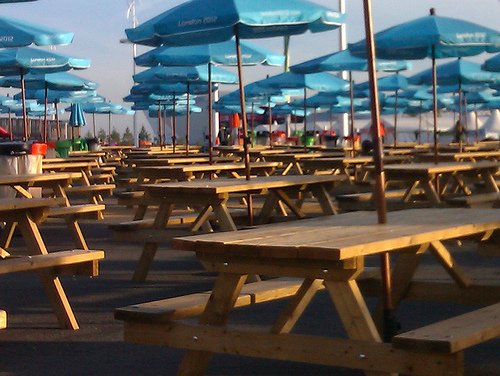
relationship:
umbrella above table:
[125, 1, 347, 37] [108, 144, 350, 279]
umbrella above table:
[0, 17, 70, 51] [4, 170, 105, 259]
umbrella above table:
[348, 6, 498, 58] [338, 139, 498, 207]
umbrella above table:
[131, 40, 286, 67] [119, 149, 236, 163]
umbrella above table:
[289, 49, 409, 76] [301, 146, 408, 172]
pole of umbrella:
[231, 48, 266, 223] [129, 2, 325, 35]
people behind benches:
[213, 116, 403, 141] [137, 145, 498, 207]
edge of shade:
[1, 332, 125, 350] [0, 335, 172, 374]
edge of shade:
[0, 334, 122, 349] [3, 338, 338, 373]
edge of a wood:
[187, 239, 337, 262] [228, 320, 260, 350]